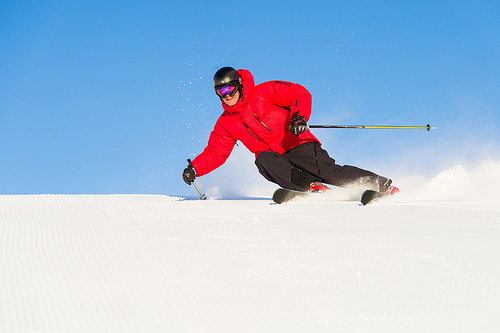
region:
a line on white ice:
[108, 247, 138, 326]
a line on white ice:
[57, 262, 82, 331]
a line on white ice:
[224, 267, 251, 329]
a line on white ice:
[300, 238, 318, 290]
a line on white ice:
[136, 220, 148, 261]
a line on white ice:
[46, 222, 58, 286]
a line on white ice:
[61, 189, 97, 271]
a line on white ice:
[203, 233, 238, 295]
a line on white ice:
[376, 240, 400, 276]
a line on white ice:
[42, 267, 54, 303]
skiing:
[38, 14, 470, 289]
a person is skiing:
[165, 48, 452, 243]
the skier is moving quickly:
[168, 42, 460, 248]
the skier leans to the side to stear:
[168, 51, 425, 234]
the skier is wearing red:
[180, 48, 457, 219]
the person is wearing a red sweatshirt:
[184, 57, 439, 222]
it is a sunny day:
[71, 27, 491, 293]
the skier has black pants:
[173, 54, 428, 226]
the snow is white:
[37, 195, 493, 327]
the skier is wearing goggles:
[160, 57, 395, 228]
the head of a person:
[207, 60, 245, 110]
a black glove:
[177, 156, 202, 187]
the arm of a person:
[191, 116, 241, 186]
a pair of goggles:
[211, 77, 243, 99]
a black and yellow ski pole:
[283, 119, 441, 139]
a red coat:
[191, 63, 326, 185]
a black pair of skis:
[270, 182, 408, 208]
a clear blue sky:
[0, 0, 498, 200]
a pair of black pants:
[248, 137, 393, 195]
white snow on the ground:
[0, 191, 499, 331]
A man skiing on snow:
[181, 62, 436, 203]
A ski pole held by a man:
[282, 115, 437, 132]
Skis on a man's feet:
[265, 182, 407, 202]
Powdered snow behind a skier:
[390, 146, 495, 201]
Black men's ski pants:
[250, 143, 397, 189]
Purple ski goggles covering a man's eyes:
[212, 78, 242, 97]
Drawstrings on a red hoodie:
[232, 105, 274, 152]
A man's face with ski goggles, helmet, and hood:
[207, 62, 256, 112]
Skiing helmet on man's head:
[210, 61, 237, 83]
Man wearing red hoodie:
[237, 67, 319, 157]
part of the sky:
[300, 14, 346, 103]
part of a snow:
[188, 214, 225, 247]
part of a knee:
[246, 144, 286, 176]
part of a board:
[268, 179, 313, 201]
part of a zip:
[251, 112, 284, 139]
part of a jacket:
[186, 135, 216, 187]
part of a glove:
[169, 153, 205, 198]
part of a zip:
[239, 119, 266, 148]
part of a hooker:
[190, 178, 213, 205]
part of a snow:
[158, 223, 186, 233]